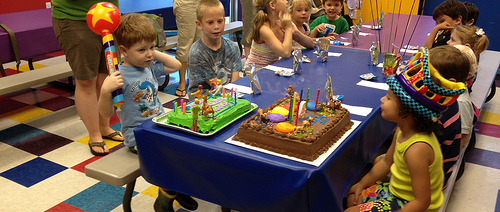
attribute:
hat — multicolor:
[382, 44, 462, 124]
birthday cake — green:
[166, 82, 241, 134]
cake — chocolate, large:
[227, 90, 354, 164]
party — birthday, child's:
[73, 0, 335, 195]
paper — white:
[354, 75, 393, 91]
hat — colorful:
[376, 41, 477, 133]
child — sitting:
[92, 19, 222, 184]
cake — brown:
[231, 73, 352, 160]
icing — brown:
[231, 131, 353, 160]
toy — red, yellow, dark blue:
[83, 1, 130, 109]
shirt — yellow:
[391, 144, 448, 208]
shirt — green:
[47, 0, 117, 20]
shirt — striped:
[442, 98, 467, 175]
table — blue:
[113, 41, 435, 197]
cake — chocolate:
[234, 73, 362, 163]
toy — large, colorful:
[83, 0, 135, 111]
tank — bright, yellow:
[386, 129, 450, 210]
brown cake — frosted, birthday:
[233, 91, 354, 161]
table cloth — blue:
[137, 35, 427, 210]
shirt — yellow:
[369, 125, 464, 210]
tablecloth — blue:
[135, 123, 305, 201]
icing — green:
[169, 103, 251, 125]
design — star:
[86, 2, 116, 27]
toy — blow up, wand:
[77, 0, 131, 110]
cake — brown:
[235, 90, 356, 162]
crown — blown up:
[386, 47, 468, 120]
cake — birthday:
[168, 93, 252, 133]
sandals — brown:
[86, 132, 130, 156]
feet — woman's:
[81, 123, 130, 157]